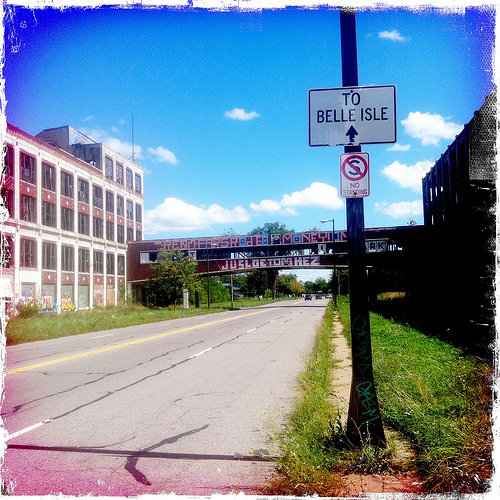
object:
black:
[348, 128, 358, 136]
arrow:
[342, 124, 358, 147]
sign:
[307, 84, 396, 149]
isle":
[357, 108, 391, 120]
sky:
[0, 0, 499, 283]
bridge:
[124, 224, 422, 283]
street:
[0, 297, 328, 500]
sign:
[338, 152, 369, 199]